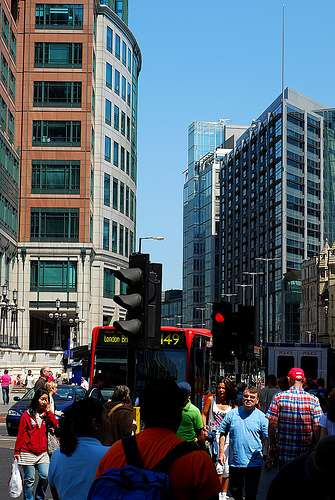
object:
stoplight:
[210, 305, 229, 330]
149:
[157, 329, 185, 352]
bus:
[85, 323, 266, 434]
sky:
[130, 4, 333, 297]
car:
[3, 376, 92, 438]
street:
[0, 426, 71, 500]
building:
[213, 91, 335, 390]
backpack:
[85, 457, 177, 500]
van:
[257, 338, 334, 401]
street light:
[253, 253, 281, 346]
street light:
[46, 292, 69, 349]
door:
[270, 346, 298, 397]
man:
[33, 364, 54, 395]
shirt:
[175, 399, 205, 446]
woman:
[9, 385, 62, 500]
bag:
[4, 458, 25, 500]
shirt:
[216, 402, 274, 475]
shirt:
[260, 382, 332, 475]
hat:
[284, 365, 309, 384]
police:
[274, 347, 297, 359]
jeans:
[17, 458, 53, 500]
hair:
[53, 396, 105, 457]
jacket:
[13, 408, 59, 460]